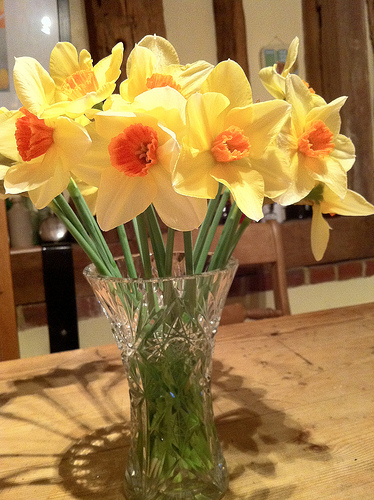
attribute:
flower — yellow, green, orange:
[84, 65, 224, 220]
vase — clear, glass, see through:
[43, 246, 269, 499]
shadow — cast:
[30, 327, 140, 491]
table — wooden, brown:
[6, 333, 371, 446]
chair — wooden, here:
[12, 232, 124, 389]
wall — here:
[160, 9, 327, 127]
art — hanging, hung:
[249, 34, 308, 99]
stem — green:
[65, 198, 283, 275]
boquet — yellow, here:
[13, 39, 356, 264]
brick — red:
[225, 242, 371, 303]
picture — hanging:
[260, 49, 325, 96]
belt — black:
[32, 242, 91, 343]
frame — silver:
[254, 42, 312, 65]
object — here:
[160, 229, 313, 328]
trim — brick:
[267, 251, 370, 303]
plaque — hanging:
[236, 37, 328, 107]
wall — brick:
[240, 236, 372, 306]